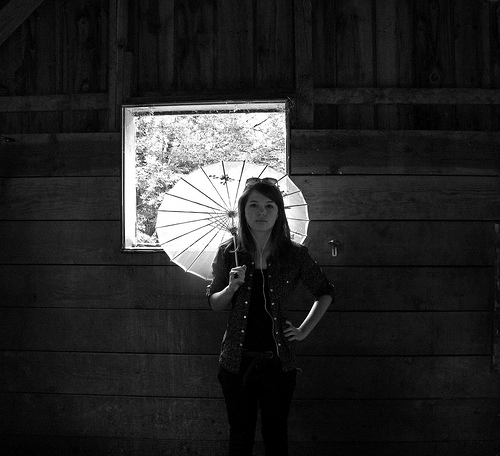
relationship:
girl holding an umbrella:
[205, 178, 335, 456] [155, 157, 313, 280]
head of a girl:
[238, 175, 284, 240] [205, 178, 335, 456]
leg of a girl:
[215, 353, 260, 456] [205, 178, 335, 456]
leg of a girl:
[253, 356, 292, 454] [205, 178, 335, 456]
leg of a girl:
[215, 353, 265, 453] [205, 178, 335, 456]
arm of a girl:
[280, 240, 339, 344] [205, 178, 335, 456]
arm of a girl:
[204, 234, 247, 316] [205, 178, 335, 456]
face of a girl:
[239, 189, 278, 235] [205, 178, 335, 456]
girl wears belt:
[205, 178, 335, 456] [237, 340, 275, 354]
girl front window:
[205, 178, 335, 456] [115, 96, 291, 248]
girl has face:
[205, 178, 335, 456] [237, 193, 282, 240]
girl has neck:
[205, 178, 335, 456] [250, 231, 268, 247]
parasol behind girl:
[150, 153, 320, 289] [205, 178, 335, 456]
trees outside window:
[139, 122, 209, 160] [122, 102, 289, 252]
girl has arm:
[205, 178, 335, 456] [286, 260, 340, 352]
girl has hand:
[205, 178, 335, 456] [226, 262, 249, 294]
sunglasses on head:
[244, 177, 279, 188] [230, 174, 290, 237]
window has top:
[115, 96, 291, 248] [122, 96, 291, 116]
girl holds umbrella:
[205, 178, 335, 456] [148, 153, 318, 285]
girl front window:
[205, 178, 335, 456] [122, 102, 289, 252]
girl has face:
[205, 178, 335, 456] [237, 184, 280, 236]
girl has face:
[205, 178, 335, 456] [241, 189, 281, 234]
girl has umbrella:
[205, 178, 335, 456] [155, 157, 313, 280]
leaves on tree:
[138, 135, 164, 153] [136, 113, 266, 233]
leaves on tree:
[215, 135, 233, 149] [133, 114, 285, 235]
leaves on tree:
[184, 138, 201, 158] [134, 108, 280, 248]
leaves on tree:
[136, 163, 153, 182] [133, 114, 285, 235]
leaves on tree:
[195, 150, 208, 160] [133, 114, 285, 235]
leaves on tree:
[139, 131, 159, 153] [128, 108, 285, 231]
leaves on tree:
[221, 129, 251, 155] [133, 114, 285, 235]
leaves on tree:
[143, 191, 163, 208] [133, 114, 285, 235]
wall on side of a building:
[0, 133, 499, 456] [2, 0, 478, 451]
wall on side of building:
[0, 133, 499, 456] [2, 0, 478, 451]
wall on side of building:
[42, 236, 189, 406] [15, 10, 475, 430]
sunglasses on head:
[244, 175, 288, 193] [240, 178, 286, 229]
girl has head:
[205, 178, 335, 456] [240, 178, 286, 229]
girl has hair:
[205, 178, 335, 456] [235, 174, 291, 259]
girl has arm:
[208, 178, 336, 436] [280, 268, 327, 351]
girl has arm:
[205, 178, 335, 456] [215, 245, 246, 315]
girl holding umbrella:
[205, 178, 335, 456] [155, 157, 313, 280]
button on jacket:
[265, 298, 277, 311] [215, 230, 333, 372]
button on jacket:
[275, 340, 282, 350] [201, 229, 335, 385]